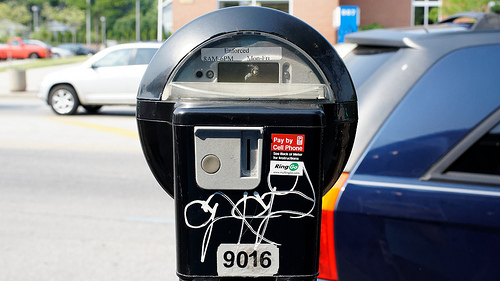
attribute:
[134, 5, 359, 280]
meter — for parking, black, painted on, number 9016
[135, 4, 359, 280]
parking meter — black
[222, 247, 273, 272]
meter number — 9016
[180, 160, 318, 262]
graffiti — white, stringy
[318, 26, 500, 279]
car — blue, parked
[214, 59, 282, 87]
display — digital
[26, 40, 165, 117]
car — white, passing back of mete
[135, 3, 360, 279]
tollbooth — for parking, black, metallic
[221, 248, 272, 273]
number — four digits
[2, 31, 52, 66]
car — red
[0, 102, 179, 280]
road — gray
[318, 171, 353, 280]
tail light — red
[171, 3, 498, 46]
building — brown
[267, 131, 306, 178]
sign — small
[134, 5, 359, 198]
circle — black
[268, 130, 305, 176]
sticker — regarding alternate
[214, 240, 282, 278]
identification — four numbers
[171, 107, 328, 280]
box — metal